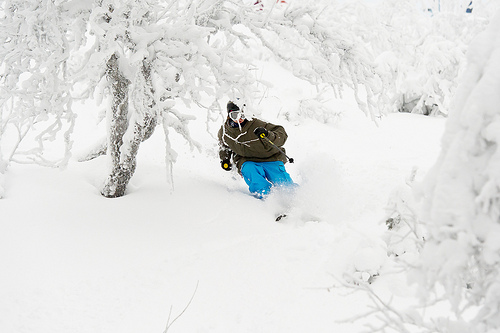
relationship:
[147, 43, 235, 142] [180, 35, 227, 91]
branches covered in snow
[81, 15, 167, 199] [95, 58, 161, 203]
tree has trunk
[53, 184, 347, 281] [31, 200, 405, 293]
snow on ground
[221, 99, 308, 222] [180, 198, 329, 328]
man on slope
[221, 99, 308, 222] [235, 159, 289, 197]
man wearing pants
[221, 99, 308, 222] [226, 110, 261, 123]
man wearing goggles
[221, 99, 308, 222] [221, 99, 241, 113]
man wearing hat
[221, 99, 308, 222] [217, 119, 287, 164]
man wearing coat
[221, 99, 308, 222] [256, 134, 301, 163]
man has pole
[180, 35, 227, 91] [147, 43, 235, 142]
snow covering branches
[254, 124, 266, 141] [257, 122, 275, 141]
gloves on hands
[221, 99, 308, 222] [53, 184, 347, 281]
man in snow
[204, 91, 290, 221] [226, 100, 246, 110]
man wearing hat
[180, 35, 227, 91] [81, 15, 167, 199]
snow on tree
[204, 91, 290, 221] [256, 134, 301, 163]
man holding pole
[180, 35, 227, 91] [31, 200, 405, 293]
snow on ground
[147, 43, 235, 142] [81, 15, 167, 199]
branches on tree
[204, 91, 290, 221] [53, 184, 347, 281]
man in snow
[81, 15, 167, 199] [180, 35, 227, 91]
tree covered with snow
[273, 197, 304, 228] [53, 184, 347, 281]
skis in snow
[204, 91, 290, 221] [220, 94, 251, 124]
man wearing mask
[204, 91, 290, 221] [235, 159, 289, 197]
man wearing pants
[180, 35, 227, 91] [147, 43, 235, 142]
snow on branches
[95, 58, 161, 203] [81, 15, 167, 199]
trunk of tree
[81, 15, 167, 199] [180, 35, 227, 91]
tree has snow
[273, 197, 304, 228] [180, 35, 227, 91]
skis in snow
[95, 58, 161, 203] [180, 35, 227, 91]
trunk has snow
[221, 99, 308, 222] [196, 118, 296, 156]
man wearing coat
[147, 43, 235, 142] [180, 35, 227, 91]
branches covered with snow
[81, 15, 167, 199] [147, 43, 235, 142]
tree has branches